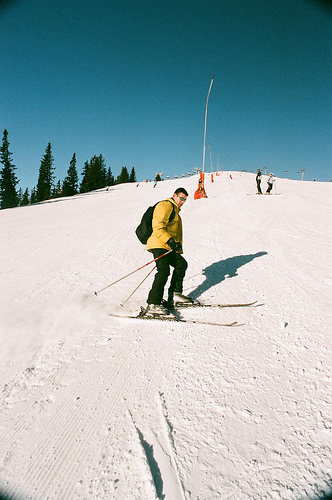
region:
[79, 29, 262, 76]
this is the sky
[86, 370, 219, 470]
this is sand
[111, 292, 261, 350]
these are snow board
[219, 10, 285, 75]
the sky is blue in color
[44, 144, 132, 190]
these are trees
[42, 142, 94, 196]
the trees are green in color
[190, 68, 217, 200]
this is a pole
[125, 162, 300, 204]
these are people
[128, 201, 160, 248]
this is a bag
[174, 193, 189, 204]
the man is wearing a spectacle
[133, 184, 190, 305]
this is a man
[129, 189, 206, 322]
the man is snow skating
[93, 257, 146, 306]
these are two sticks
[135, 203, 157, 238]
the man is carrying a bag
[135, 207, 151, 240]
the bag is black in color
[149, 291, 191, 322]
the man is wearing skiis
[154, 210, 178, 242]
the jacket is yellow in color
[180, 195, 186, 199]
the man is wearing goggles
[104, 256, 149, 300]
the poles are thin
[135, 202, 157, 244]
male skier wearing black backpack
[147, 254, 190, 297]
male skier wearing black pants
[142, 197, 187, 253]
male skier wearing gold colored jacket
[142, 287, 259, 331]
male skier wearing black boots and skis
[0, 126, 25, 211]
green leaves on trees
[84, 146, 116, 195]
green leaves on trees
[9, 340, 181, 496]
tracks in white snow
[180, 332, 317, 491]
white snow on mountain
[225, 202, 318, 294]
white snow on mountain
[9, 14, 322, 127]
dark blue cloudless sky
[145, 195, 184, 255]
yellow jacket on skier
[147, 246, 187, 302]
black pants on skier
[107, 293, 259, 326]
a pair of skis on the mountain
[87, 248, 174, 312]
a pair of red and white ski poles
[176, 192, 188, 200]
a pair of sunglasses on the skier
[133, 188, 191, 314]
a man skiing on the mountain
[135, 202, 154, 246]
a large black backpack on the skier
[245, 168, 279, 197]
two people standing on the mountain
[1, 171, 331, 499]
a snow-covered mountain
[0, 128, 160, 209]
a group of trees on the mountain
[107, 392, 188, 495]
TRACKS IN THE SNOW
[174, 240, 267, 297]
A SHADOW ON SNOW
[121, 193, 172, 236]
A BLACK BACKPACK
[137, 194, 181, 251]
A YELLOW SKI JACKET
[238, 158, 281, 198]
TWO PEOPLE ON SKIS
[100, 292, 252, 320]
A PAIR OF SKIS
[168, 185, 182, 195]
A PAIR OF SUNGLASSES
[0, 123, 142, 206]
TREES IN THE BACKGROUND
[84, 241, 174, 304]
A PAIR OF SKI POLES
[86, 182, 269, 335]
A MAN ON SKIS